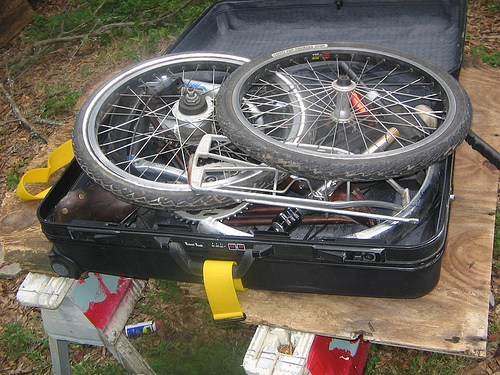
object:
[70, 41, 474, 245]
bike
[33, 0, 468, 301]
suitcase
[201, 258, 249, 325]
strap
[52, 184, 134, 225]
seat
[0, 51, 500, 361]
wood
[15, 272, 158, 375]
saw horse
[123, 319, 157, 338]
can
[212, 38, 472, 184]
tire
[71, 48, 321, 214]
tire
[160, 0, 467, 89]
lid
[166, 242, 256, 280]
handle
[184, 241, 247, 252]
lock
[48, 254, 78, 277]
wheel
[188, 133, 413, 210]
bike rack